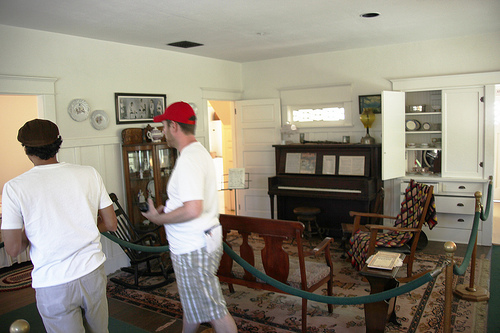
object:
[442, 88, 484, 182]
cabinet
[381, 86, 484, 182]
cabinet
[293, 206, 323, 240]
stool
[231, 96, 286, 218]
door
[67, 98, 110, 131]
two plates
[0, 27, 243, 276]
wall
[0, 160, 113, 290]
t shirt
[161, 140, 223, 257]
t shirt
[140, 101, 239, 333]
man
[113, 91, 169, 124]
picture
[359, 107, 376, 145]
cup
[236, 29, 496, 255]
wall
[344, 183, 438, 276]
blanket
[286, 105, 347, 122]
window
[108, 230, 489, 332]
rug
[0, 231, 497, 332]
floor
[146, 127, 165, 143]
tea kettle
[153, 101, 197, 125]
cap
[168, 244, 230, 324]
shorts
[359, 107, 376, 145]
lamp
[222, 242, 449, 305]
rope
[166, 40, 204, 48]
vent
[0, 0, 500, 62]
ceiling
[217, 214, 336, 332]
bench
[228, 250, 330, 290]
cushion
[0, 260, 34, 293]
rug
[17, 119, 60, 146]
brown hat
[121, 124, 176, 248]
curio cabinet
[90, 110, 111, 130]
plate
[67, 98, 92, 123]
plate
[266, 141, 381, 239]
piano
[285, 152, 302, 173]
mic sheets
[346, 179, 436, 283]
rocker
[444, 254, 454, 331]
stick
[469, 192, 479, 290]
stick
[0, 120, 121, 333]
man